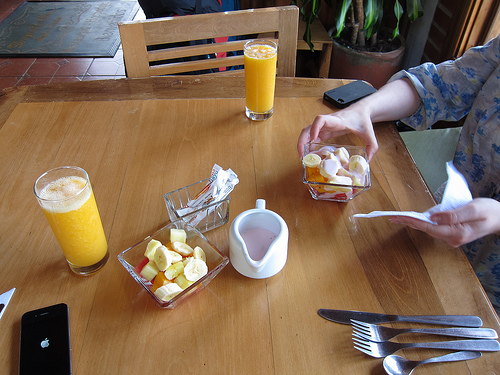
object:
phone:
[323, 80, 378, 106]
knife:
[317, 306, 484, 328]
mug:
[229, 198, 290, 278]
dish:
[163, 175, 230, 235]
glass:
[245, 39, 277, 121]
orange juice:
[39, 175, 109, 267]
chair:
[118, 1, 302, 83]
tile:
[53, 56, 95, 77]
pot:
[330, 39, 408, 90]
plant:
[300, 1, 424, 50]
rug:
[1, 0, 146, 59]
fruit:
[300, 151, 324, 169]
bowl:
[298, 137, 374, 205]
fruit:
[155, 283, 183, 302]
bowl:
[115, 216, 229, 311]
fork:
[349, 318, 500, 341]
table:
[2, 78, 500, 375]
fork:
[349, 336, 500, 359]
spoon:
[383, 348, 478, 375]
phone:
[15, 302, 74, 375]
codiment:
[178, 163, 235, 228]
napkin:
[352, 162, 474, 225]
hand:
[385, 196, 500, 249]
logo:
[40, 337, 52, 348]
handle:
[255, 197, 265, 209]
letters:
[89, 36, 115, 41]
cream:
[179, 163, 223, 210]